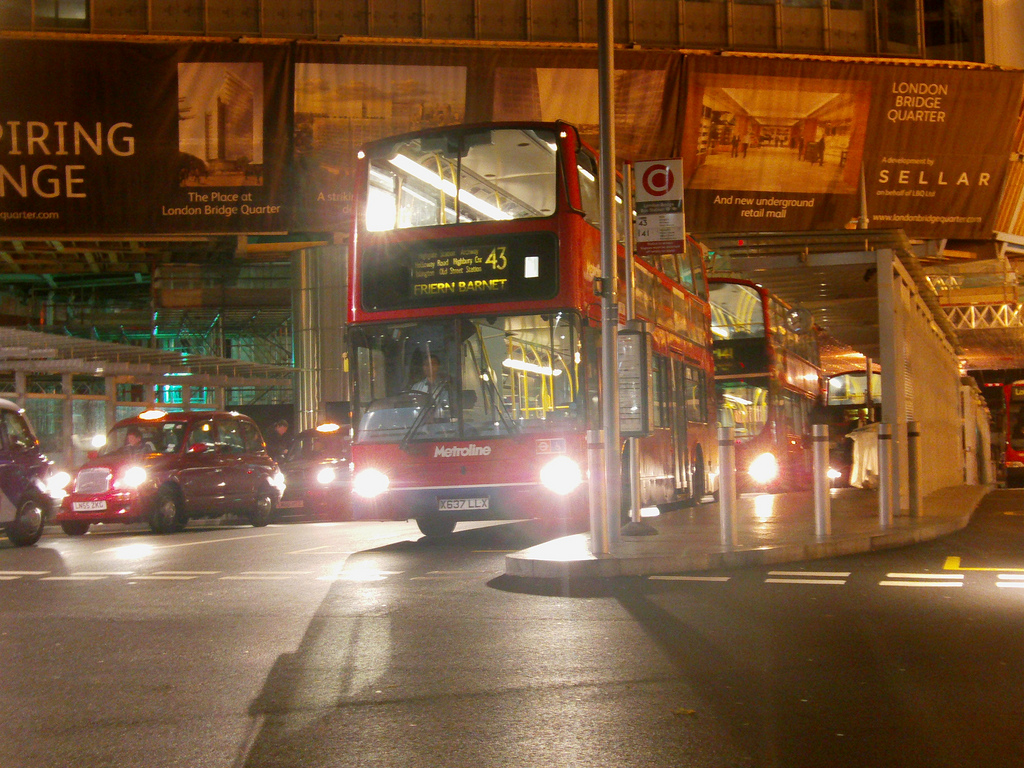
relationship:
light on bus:
[513, 430, 598, 523] [329, 115, 863, 638]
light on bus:
[108, 383, 191, 436] [68, 363, 321, 618]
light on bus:
[506, 247, 573, 297] [303, 96, 848, 591]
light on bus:
[731, 431, 788, 494] [687, 260, 841, 557]